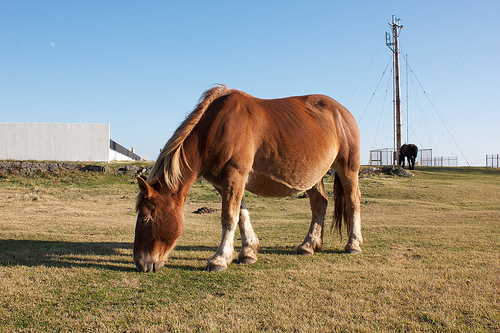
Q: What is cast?
A: Shadow.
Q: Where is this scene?
A: Field.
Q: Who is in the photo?
A: No one.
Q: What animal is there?
A: Horse.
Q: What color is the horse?
A: Brown.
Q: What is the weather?
A: Sunny.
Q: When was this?
A: Daytime.